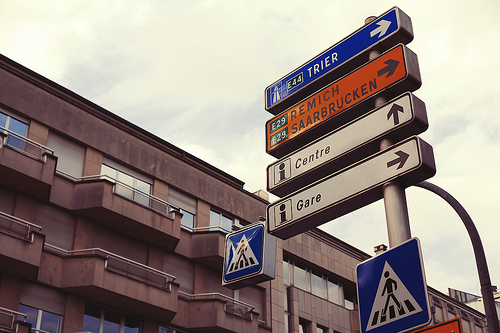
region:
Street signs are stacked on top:
[242, 38, 466, 248]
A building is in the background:
[11, 50, 207, 328]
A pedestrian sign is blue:
[335, 253, 497, 330]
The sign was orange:
[265, 72, 498, 149]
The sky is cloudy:
[97, 40, 244, 133]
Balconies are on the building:
[65, 163, 204, 326]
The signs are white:
[265, 148, 462, 228]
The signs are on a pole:
[252, 45, 427, 229]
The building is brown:
[4, 54, 86, 311]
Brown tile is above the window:
[295, 235, 347, 331]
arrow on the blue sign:
[367, 12, 389, 43]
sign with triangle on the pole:
[350, 235, 430, 330]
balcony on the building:
[102, 188, 174, 220]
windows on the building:
[30, 298, 67, 331]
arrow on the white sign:
[379, 146, 421, 174]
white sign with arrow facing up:
[382, 100, 406, 130]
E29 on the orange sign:
[269, 116, 290, 131]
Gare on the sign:
[295, 189, 327, 213]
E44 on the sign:
[281, 70, 306, 95]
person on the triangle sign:
[380, 265, 405, 320]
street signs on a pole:
[235, 16, 434, 237]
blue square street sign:
[347, 237, 446, 331]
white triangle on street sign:
[368, 254, 422, 331]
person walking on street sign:
[363, 256, 414, 324]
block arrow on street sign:
[385, 146, 416, 171]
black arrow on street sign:
[360, 97, 408, 147]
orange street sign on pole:
[244, 48, 409, 139]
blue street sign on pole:
[254, 10, 399, 105]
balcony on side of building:
[72, 168, 184, 244]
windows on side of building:
[91, 166, 162, 199]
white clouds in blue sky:
[28, 5, 75, 39]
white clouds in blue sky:
[104, 8, 156, 85]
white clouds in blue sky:
[180, 33, 220, 108]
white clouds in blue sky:
[185, 82, 237, 157]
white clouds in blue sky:
[225, 21, 272, 49]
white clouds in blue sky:
[430, 11, 490, 87]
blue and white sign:
[323, 241, 424, 318]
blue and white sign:
[217, 231, 273, 278]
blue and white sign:
[271, 15, 386, 62]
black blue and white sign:
[211, 223, 272, 274]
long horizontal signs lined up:
[260, 5, 436, 235]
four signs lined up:
[265, 6, 439, 239]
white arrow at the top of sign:
[370, 22, 387, 36]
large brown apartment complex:
[0, 58, 491, 331]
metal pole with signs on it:
[360, 18, 498, 331]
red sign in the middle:
[260, 43, 422, 158]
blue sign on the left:
[218, 222, 276, 286]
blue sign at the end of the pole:
[354, 235, 429, 329]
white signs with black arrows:
[268, 92, 435, 240]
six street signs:
[219, 6, 436, 330]